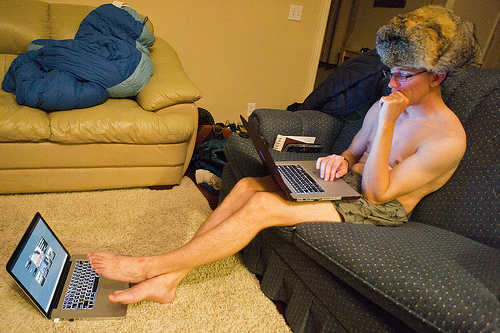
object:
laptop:
[241, 113, 357, 203]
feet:
[86, 251, 177, 304]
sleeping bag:
[102, 8, 156, 117]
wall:
[206, 1, 324, 108]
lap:
[239, 181, 368, 228]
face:
[388, 64, 430, 106]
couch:
[0, 0, 199, 195]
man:
[290, 1, 480, 235]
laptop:
[266, 155, 364, 209]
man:
[86, 6, 482, 304]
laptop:
[7, 209, 128, 319]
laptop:
[237, 109, 362, 205]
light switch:
[285, 0, 306, 24]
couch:
[215, 63, 500, 333]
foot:
[88, 251, 152, 284]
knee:
[231, 174, 278, 221]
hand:
[315, 154, 349, 182]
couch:
[0, 0, 204, 195]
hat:
[374, 3, 484, 77]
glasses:
[382, 69, 426, 81]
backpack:
[196, 124, 233, 148]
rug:
[0, 174, 295, 333]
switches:
[286, 2, 309, 25]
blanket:
[0, 1, 154, 111]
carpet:
[2, 175, 292, 333]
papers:
[272, 134, 323, 153]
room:
[4, 3, 492, 310]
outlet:
[247, 102, 256, 116]